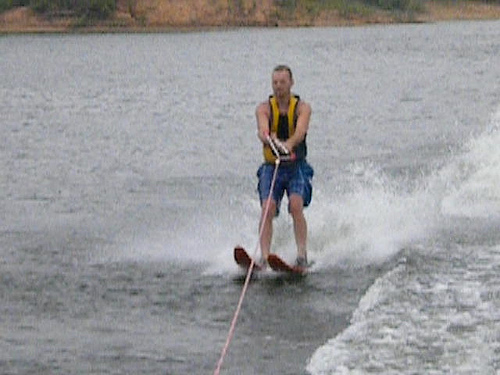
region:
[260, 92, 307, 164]
a yellow life vest on a man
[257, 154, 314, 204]
blue plaid shorts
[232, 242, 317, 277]
water skis on a man's feet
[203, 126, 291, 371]
a line pulling a water skier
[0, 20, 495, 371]
dark lake water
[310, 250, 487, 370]
wake behind a boat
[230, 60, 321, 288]
a man water skiing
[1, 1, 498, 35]
a dirt hill along the wate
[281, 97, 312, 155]
a bare left arm on a man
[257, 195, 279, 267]
a bare right leg on a man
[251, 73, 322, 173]
the life vest is yellow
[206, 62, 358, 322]
the life vest is yellow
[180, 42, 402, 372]
man is holding a rope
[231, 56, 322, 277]
a man water skiing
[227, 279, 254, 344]
a man being pulled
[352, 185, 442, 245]
a splash of water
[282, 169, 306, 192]
man wearing shorts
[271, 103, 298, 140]
man wearing a vest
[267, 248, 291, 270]
the man is wearing skiis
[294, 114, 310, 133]
the mans arm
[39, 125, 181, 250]
the water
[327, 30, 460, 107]
the oceans water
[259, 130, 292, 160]
the man is holding on to an object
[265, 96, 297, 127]
a vest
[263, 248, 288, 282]
the skii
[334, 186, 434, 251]
the water is white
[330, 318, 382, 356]
bubbles in the water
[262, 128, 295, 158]
man is holding an object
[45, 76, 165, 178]
the water is blue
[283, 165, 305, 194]
the man is wearing blue shorts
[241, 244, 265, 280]
The man is being pulled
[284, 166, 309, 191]
man is wearing shorts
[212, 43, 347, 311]
The man is wearing water skis.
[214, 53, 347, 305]
The water skis are in the air.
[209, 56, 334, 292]
The man is wearing shorts.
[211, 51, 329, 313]
The man is wearing a life vest.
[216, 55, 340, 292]
The man's shorts are plaid.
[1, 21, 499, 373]
The water is splashing.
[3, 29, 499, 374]
The water is wavy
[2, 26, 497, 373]
The water is rippling.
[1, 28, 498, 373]
The water is temperate.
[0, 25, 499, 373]
The water buoyant.